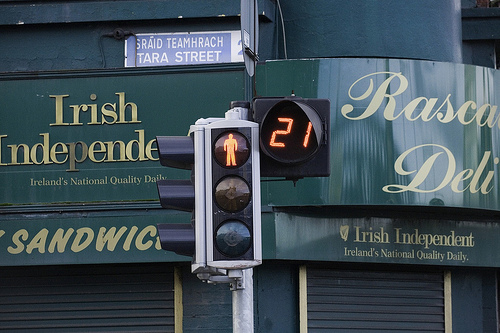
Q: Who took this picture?
A: The photographer.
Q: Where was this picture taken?
A: On Tara Street.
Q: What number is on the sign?
A: 21.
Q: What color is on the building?
A: Green.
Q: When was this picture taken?
A: During the day.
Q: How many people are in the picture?
A: None.